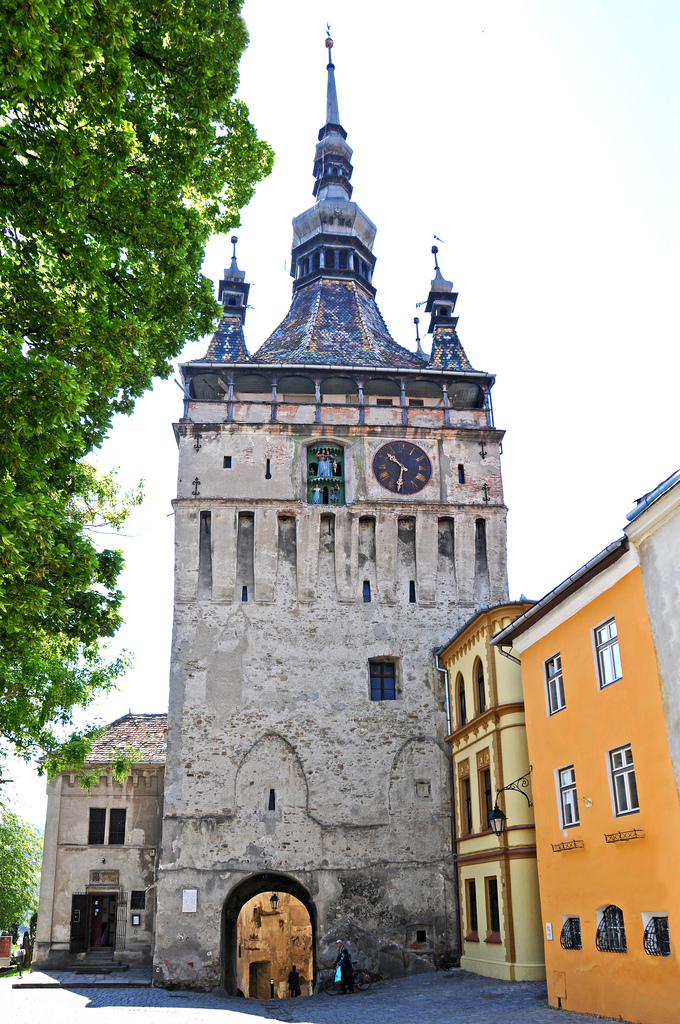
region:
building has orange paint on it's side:
[485, 538, 679, 1021]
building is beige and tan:
[433, 597, 551, 982]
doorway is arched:
[218, 866, 322, 1009]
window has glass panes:
[366, 657, 402, 705]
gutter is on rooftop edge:
[492, 533, 627, 654]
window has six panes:
[367, 659, 400, 702]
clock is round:
[370, 438, 433, 499]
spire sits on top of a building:
[310, 18, 359, 200]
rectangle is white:
[177, 885, 200, 914]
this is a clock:
[341, 426, 452, 527]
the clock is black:
[348, 428, 449, 509]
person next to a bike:
[309, 934, 396, 1014]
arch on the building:
[198, 862, 336, 1006]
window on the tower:
[338, 639, 413, 729]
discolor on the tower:
[282, 843, 458, 1005]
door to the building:
[45, 891, 139, 972]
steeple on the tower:
[291, 27, 410, 391]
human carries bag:
[331, 939, 359, 996]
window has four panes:
[608, 745, 642, 816]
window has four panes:
[553, 766, 582, 831]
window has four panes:
[543, 654, 567, 721]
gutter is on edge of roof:
[490, 536, 630, 664]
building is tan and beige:
[437, 595, 546, 978]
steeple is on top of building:
[289, 20, 379, 284]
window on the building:
[658, 926, 667, 948]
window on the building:
[592, 901, 625, 956]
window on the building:
[558, 915, 579, 949]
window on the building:
[544, 755, 584, 826]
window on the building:
[534, 670, 572, 714]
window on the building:
[596, 670, 640, 702]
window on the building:
[481, 865, 508, 954]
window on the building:
[457, 880, 476, 948]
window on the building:
[470, 745, 500, 835]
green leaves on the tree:
[118, 156, 164, 213]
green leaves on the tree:
[24, 710, 124, 804]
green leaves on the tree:
[14, 612, 92, 695]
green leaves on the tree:
[31, 552, 120, 647]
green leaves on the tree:
[30, 534, 121, 628]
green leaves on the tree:
[4, 827, 33, 884]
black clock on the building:
[366, 435, 430, 496]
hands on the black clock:
[389, 450, 413, 489]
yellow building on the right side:
[499, 524, 678, 1008]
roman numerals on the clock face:
[367, 437, 430, 492]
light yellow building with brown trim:
[442, 608, 534, 982]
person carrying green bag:
[330, 941, 351, 988]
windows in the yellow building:
[527, 610, 666, 959]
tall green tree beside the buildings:
[6, 6, 218, 972]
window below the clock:
[355, 647, 404, 702]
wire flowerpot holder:
[599, 829, 646, 842]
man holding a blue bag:
[323, 938, 357, 997]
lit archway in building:
[233, 892, 308, 994]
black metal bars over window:
[597, 909, 632, 956]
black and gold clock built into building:
[367, 438, 443, 496]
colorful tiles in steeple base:
[280, 286, 393, 356]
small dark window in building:
[359, 644, 407, 705]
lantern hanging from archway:
[266, 889, 279, 908]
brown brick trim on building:
[497, 862, 517, 957]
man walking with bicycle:
[324, 944, 381, 993]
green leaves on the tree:
[64, 304, 89, 362]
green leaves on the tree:
[48, 591, 84, 678]